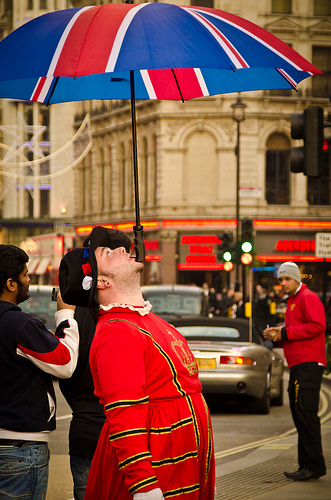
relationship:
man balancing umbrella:
[58, 245, 224, 498] [0, 3, 323, 106]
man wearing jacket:
[58, 245, 224, 498] [84, 301, 217, 499]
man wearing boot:
[260, 260, 329, 481] [282, 462, 330, 484]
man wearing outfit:
[58, 245, 224, 498] [84, 301, 217, 499]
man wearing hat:
[58, 245, 224, 498] [57, 225, 109, 324]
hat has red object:
[57, 225, 109, 324] [81, 262, 92, 275]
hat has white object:
[57, 225, 109, 324] [81, 275, 94, 291]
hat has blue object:
[57, 225, 109, 324] [81, 245, 92, 257]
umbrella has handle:
[2, 3, 325, 266] [125, 71, 148, 262]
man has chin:
[58, 245, 224, 498] [131, 252, 147, 274]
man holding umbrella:
[58, 245, 224, 498] [2, 3, 325, 266]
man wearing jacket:
[1, 243, 82, 499] [0, 299, 82, 443]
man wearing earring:
[58, 245, 224, 498] [104, 280, 112, 287]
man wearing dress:
[58, 245, 224, 498] [84, 301, 217, 499]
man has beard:
[1, 243, 82, 499] [13, 274, 31, 304]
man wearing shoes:
[260, 260, 329, 481] [282, 462, 330, 484]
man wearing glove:
[58, 245, 224, 498] [129, 484, 168, 498]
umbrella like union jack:
[2, 3, 325, 266] [29, 4, 259, 104]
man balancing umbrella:
[58, 245, 224, 498] [2, 3, 325, 266]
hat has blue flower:
[57, 225, 109, 324] [81, 245, 92, 257]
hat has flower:
[57, 225, 109, 324] [81, 262, 92, 275]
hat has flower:
[57, 225, 109, 324] [81, 275, 94, 291]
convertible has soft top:
[164, 317, 287, 413] [166, 316, 277, 345]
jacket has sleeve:
[0, 299, 82, 443] [17, 310, 81, 379]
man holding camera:
[1, 243, 82, 499] [50, 286, 64, 302]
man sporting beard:
[1, 243, 82, 499] [13, 274, 31, 304]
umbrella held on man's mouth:
[2, 3, 325, 266] [128, 253, 146, 269]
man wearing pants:
[260, 260, 329, 481] [284, 362, 327, 469]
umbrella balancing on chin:
[2, 3, 325, 266] [131, 252, 147, 274]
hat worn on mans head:
[57, 225, 109, 324] [86, 245, 146, 309]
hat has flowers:
[57, 225, 109, 324] [80, 249, 94, 292]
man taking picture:
[1, 243, 82, 499] [52, 288, 73, 308]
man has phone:
[1, 243, 82, 499] [49, 288, 61, 302]